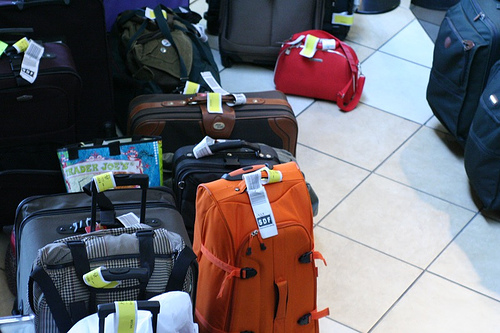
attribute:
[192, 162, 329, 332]
luggage — orange, standing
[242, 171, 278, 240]
tag — yellow, white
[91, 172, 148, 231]
luggage handle — black, sticking up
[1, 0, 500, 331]
tile — diaganol, white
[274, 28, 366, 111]
bag — black, white, small, red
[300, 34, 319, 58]
tag — yellow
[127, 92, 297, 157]
luggage — black, brown, two-toned, older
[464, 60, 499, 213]
luggage — black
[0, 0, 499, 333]
floor — ceramic, tiled, white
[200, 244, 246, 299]
strap — orange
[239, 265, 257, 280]
buckle — black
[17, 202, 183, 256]
zipper — black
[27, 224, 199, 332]
bag — checkered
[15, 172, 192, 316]
luggage — gray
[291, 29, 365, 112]
strap — red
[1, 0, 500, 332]
bags — inside, together, grouped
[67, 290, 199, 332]
luggage — white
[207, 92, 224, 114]
tag — yellow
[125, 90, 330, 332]
luggages — lined up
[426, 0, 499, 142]
luggage — black